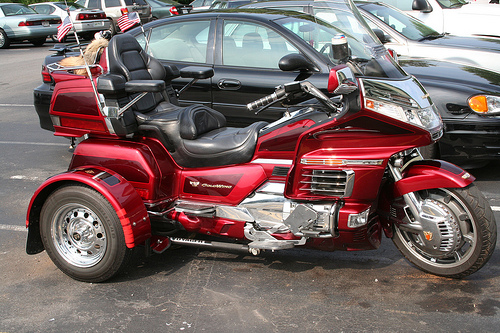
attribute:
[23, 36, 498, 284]
bike — parked, alone, red, silver, shiny, metal, red in color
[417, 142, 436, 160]
tire — black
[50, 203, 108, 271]
rim — silver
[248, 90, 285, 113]
handle — silver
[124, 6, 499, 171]
car — black, parked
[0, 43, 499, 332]
street — black, wet, paved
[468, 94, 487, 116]
light — yellow, yellow colored, colored yellow, a yellow color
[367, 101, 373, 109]
light — yellow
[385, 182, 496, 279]
tire — small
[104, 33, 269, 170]
seat — leather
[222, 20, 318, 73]
window — closed